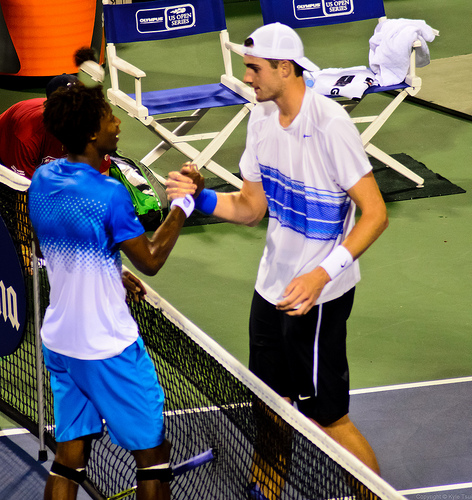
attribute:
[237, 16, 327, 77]
cap — white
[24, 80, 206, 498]
person — white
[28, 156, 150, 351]
top — blue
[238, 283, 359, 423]
shorts — black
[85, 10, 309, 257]
chair — folding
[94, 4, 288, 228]
chair — white, blue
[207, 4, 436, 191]
chair — white, blue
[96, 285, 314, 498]
net — black, white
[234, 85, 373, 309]
shirt — blue, white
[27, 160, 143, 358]
shirt — blue, white